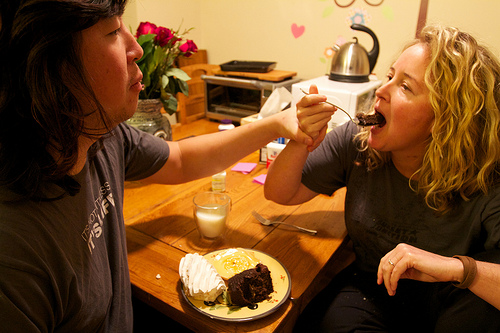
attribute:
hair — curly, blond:
[415, 23, 497, 203]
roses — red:
[137, 21, 202, 58]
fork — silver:
[252, 209, 322, 238]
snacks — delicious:
[228, 260, 277, 318]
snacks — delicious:
[175, 248, 224, 309]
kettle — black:
[331, 17, 389, 86]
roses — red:
[175, 40, 200, 60]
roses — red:
[153, 24, 176, 49]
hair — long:
[0, 2, 129, 205]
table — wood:
[111, 120, 351, 330]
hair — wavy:
[359, 28, 497, 206]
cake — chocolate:
[224, 260, 284, 312]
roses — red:
[159, 52, 179, 90]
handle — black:
[360, 51, 380, 101]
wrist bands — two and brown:
[463, 254, 475, 324]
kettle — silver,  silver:
[326, 15, 385, 80]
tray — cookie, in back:
[210, 96, 263, 117]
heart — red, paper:
[287, 18, 309, 39]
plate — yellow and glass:
[176, 235, 293, 326]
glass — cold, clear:
[190, 192, 235, 240]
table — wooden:
[172, 112, 229, 143]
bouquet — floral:
[129, 20, 203, 127]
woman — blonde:
[296, 21, 498, 326]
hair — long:
[419, 20, 495, 273]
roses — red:
[129, 12, 197, 58]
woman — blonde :
[417, 13, 497, 222]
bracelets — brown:
[455, 238, 481, 287]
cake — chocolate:
[227, 265, 276, 303]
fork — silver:
[250, 207, 320, 243]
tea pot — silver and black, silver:
[325, 16, 386, 95]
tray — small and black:
[219, 52, 278, 78]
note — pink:
[233, 158, 253, 175]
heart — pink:
[286, 18, 310, 42]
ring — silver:
[385, 256, 398, 268]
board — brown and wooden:
[212, 66, 296, 86]